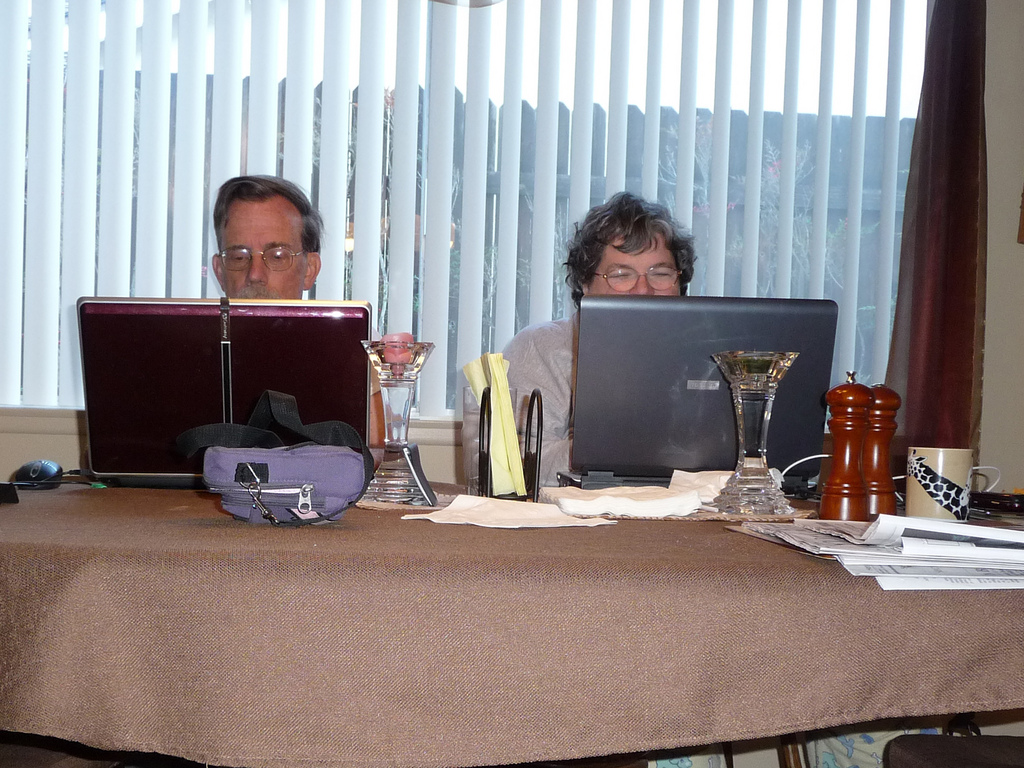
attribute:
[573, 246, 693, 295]
eyeglasses — pair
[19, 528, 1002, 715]
tablecloth — tan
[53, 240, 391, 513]
computer — laptop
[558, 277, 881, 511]
computer — laptop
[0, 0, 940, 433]
blinds — white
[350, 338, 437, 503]
candlestick holder — glass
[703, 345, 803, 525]
candlestick holder — glass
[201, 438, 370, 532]
pouch — purple